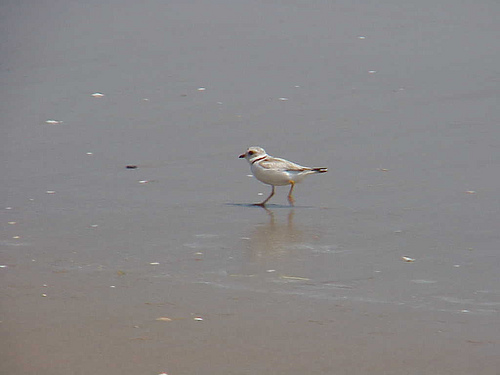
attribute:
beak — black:
[236, 154, 246, 161]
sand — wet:
[0, 27, 494, 372]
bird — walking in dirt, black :
[233, 140, 327, 212]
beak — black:
[235, 149, 249, 161]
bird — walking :
[223, 138, 333, 215]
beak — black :
[225, 145, 249, 165]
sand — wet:
[237, 226, 284, 247]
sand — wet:
[343, 300, 455, 373]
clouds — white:
[34, 20, 228, 91]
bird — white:
[233, 137, 335, 212]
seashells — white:
[43, 113, 67, 129]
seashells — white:
[89, 85, 106, 102]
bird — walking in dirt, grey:
[238, 147, 326, 208]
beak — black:
[238, 147, 247, 159]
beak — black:
[237, 151, 246, 161]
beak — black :
[226, 145, 252, 186]